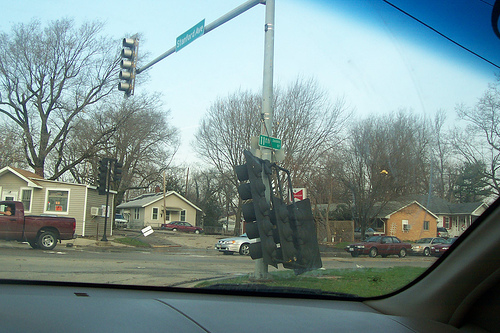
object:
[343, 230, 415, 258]
car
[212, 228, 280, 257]
car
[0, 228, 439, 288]
road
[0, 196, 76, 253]
truck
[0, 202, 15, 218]
driver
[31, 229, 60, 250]
tire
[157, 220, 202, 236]
car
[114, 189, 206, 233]
house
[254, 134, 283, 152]
road sign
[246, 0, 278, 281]
post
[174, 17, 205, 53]
road sign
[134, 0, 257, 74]
post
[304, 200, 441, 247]
building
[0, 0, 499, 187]
sky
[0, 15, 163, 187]
tree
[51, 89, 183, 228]
tree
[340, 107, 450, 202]
tree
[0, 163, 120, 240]
house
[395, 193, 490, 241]
house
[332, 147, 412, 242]
tree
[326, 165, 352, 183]
branch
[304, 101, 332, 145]
branch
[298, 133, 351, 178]
branch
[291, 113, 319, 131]
branch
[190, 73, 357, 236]
tree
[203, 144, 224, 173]
branch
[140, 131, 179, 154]
branch